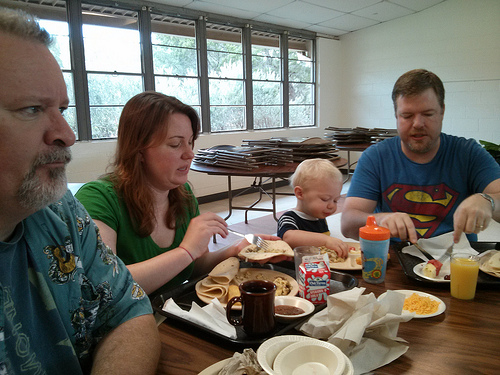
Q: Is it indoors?
A: Yes, it is indoors.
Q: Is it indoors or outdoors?
A: It is indoors.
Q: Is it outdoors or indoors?
A: It is indoors.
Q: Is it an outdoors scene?
A: No, it is indoors.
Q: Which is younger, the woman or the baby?
A: The baby is younger than the woman.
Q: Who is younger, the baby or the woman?
A: The baby is younger than the woman.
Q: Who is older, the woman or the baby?
A: The woman is older than the baby.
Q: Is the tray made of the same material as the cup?
A: Yes, both the tray and the cup are made of plastic.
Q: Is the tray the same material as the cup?
A: Yes, both the tray and the cup are made of plastic.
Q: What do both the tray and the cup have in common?
A: The material, both the tray and the cup are plastic.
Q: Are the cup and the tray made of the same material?
A: Yes, both the cup and the tray are made of plastic.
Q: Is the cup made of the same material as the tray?
A: Yes, both the cup and the tray are made of plastic.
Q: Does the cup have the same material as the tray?
A: Yes, both the cup and the tray are made of plastic.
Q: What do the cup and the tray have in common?
A: The material, both the cup and the tray are plastic.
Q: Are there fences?
A: No, there are no fences.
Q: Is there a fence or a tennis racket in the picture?
A: No, there are no fences or rackets.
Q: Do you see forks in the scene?
A: Yes, there is a fork.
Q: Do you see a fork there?
A: Yes, there is a fork.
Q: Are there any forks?
A: Yes, there is a fork.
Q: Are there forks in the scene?
A: Yes, there is a fork.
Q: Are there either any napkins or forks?
A: Yes, there is a fork.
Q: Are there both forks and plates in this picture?
A: Yes, there are both a fork and plates.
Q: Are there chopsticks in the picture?
A: No, there are no chopsticks.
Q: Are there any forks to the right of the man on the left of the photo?
A: Yes, there is a fork to the right of the man.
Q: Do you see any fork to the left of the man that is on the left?
A: No, the fork is to the right of the man.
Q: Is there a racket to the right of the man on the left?
A: No, there is a fork to the right of the man.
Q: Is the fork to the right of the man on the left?
A: Yes, the fork is to the right of the man.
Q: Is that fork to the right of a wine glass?
A: No, the fork is to the right of the man.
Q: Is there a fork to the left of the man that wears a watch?
A: Yes, there is a fork to the left of the man.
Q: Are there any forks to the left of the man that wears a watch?
A: Yes, there is a fork to the left of the man.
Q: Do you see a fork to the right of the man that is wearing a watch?
A: No, the fork is to the left of the man.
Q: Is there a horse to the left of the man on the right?
A: No, there is a fork to the left of the man.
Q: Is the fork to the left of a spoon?
A: No, the fork is to the left of the man.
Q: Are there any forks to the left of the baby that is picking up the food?
A: Yes, there is a fork to the left of the baby.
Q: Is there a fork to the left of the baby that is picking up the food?
A: Yes, there is a fork to the left of the baby.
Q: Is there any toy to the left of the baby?
A: No, there is a fork to the left of the baby.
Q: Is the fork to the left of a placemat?
A: No, the fork is to the left of the baby.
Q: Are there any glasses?
A: No, there are no glasses.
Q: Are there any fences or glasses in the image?
A: No, there are no glasses or fences.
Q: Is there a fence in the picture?
A: No, there are no fences.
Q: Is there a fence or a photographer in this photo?
A: No, there are no fences or photographers.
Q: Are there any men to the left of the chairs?
A: Yes, there is a man to the left of the chairs.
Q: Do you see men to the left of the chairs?
A: Yes, there is a man to the left of the chairs.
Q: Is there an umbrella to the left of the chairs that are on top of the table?
A: No, there is a man to the left of the chairs.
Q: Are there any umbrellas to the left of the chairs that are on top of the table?
A: No, there is a man to the left of the chairs.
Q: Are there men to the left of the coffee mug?
A: Yes, there is a man to the left of the coffee mug.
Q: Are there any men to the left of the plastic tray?
A: Yes, there is a man to the left of the tray.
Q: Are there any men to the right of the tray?
A: No, the man is to the left of the tray.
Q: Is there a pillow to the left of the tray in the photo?
A: No, there is a man to the left of the tray.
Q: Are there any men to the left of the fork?
A: Yes, there is a man to the left of the fork.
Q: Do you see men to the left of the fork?
A: Yes, there is a man to the left of the fork.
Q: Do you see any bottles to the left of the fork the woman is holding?
A: No, there is a man to the left of the fork.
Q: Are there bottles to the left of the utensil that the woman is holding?
A: No, there is a man to the left of the fork.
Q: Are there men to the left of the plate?
A: Yes, there is a man to the left of the plate.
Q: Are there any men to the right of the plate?
A: No, the man is to the left of the plate.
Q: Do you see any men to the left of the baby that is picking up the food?
A: Yes, there is a man to the left of the baby.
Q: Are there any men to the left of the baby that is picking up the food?
A: Yes, there is a man to the left of the baby.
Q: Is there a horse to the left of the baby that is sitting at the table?
A: No, there is a man to the left of the baby.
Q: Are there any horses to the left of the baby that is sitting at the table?
A: No, there is a man to the left of the baby.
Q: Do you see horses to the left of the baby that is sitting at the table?
A: No, there is a man to the left of the baby.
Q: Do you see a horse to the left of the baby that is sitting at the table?
A: No, there is a man to the left of the baby.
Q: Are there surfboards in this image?
A: No, there are no surfboards.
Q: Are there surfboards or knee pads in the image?
A: No, there are no surfboards or knee pads.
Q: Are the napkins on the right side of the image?
A: Yes, the napkins are on the right of the image.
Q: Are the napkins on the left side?
A: No, the napkins are on the right of the image.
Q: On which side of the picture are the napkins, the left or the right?
A: The napkins are on the right of the image.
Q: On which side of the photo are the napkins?
A: The napkins are on the right of the image.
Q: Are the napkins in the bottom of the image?
A: Yes, the napkins are in the bottom of the image.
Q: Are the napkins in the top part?
A: No, the napkins are in the bottom of the image.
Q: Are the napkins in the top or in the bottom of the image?
A: The napkins are in the bottom of the image.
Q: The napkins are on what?
A: The napkins are on the table.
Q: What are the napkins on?
A: The napkins are on the table.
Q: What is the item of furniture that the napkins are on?
A: The piece of furniture is a table.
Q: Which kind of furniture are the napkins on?
A: The napkins are on the table.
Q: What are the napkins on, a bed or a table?
A: The napkins are on a table.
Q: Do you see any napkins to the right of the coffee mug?
A: Yes, there are napkins to the right of the coffee mug.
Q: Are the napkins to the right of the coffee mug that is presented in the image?
A: Yes, the napkins are to the right of the coffee mug.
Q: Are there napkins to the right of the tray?
A: Yes, there are napkins to the right of the tray.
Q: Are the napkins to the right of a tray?
A: Yes, the napkins are to the right of a tray.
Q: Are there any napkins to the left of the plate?
A: No, the napkins are to the right of the plate.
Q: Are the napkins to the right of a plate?
A: Yes, the napkins are to the right of a plate.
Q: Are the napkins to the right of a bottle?
A: No, the napkins are to the right of a plate.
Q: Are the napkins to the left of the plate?
A: No, the napkins are to the right of the plate.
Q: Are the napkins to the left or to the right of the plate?
A: The napkins are to the right of the plate.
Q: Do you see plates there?
A: Yes, there is a plate.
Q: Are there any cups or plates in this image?
A: Yes, there is a plate.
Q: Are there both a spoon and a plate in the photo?
A: No, there is a plate but no spoons.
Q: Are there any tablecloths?
A: No, there are no tablecloths.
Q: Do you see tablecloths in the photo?
A: No, there are no tablecloths.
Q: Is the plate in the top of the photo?
A: No, the plate is in the bottom of the image.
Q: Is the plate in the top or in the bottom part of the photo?
A: The plate is in the bottom of the image.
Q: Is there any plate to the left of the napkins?
A: Yes, there is a plate to the left of the napkins.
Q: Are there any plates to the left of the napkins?
A: Yes, there is a plate to the left of the napkins.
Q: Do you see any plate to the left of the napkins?
A: Yes, there is a plate to the left of the napkins.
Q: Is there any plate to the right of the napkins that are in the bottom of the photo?
A: No, the plate is to the left of the napkins.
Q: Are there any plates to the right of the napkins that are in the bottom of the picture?
A: No, the plate is to the left of the napkins.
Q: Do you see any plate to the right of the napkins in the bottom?
A: No, the plate is to the left of the napkins.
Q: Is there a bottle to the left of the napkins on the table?
A: No, there is a plate to the left of the napkins.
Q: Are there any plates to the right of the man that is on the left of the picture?
A: Yes, there is a plate to the right of the man.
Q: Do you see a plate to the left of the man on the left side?
A: No, the plate is to the right of the man.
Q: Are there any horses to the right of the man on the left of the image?
A: No, there is a plate to the right of the man.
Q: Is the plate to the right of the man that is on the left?
A: Yes, the plate is to the right of the man.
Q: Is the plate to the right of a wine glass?
A: No, the plate is to the right of the man.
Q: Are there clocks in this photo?
A: No, there are no clocks.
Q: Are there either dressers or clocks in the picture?
A: No, there are no clocks or dressers.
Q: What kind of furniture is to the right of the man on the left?
A: The pieces of furniture are chairs.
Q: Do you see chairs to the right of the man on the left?
A: Yes, there are chairs to the right of the man.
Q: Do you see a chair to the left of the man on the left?
A: No, the chairs are to the right of the man.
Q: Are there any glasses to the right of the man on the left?
A: No, there are chairs to the right of the man.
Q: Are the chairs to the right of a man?
A: Yes, the chairs are to the right of a man.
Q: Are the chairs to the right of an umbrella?
A: No, the chairs are to the right of a man.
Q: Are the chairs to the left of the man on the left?
A: No, the chairs are to the right of the man.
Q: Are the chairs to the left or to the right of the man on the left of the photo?
A: The chairs are to the right of the man.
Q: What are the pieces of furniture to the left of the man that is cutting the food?
A: The pieces of furniture are chairs.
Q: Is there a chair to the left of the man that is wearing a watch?
A: Yes, there are chairs to the left of the man.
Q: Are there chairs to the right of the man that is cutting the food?
A: No, the chairs are to the left of the man.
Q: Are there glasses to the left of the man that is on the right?
A: No, there are chairs to the left of the man.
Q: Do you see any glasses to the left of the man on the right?
A: No, there are chairs to the left of the man.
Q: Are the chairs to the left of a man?
A: Yes, the chairs are to the left of a man.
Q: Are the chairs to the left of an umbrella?
A: No, the chairs are to the left of a man.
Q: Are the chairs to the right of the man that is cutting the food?
A: No, the chairs are to the left of the man.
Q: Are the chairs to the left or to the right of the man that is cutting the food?
A: The chairs are to the left of the man.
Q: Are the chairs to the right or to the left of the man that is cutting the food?
A: The chairs are to the left of the man.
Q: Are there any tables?
A: Yes, there is a table.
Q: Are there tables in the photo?
A: Yes, there is a table.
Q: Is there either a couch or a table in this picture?
A: Yes, there is a table.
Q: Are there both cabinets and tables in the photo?
A: No, there is a table but no cabinets.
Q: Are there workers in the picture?
A: No, there are no workers.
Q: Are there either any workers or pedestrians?
A: No, there are no workers or pedestrians.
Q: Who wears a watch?
A: The man wears a watch.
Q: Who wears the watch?
A: The man wears a watch.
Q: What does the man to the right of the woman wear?
A: The man wears a watch.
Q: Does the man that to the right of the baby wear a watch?
A: Yes, the man wears a watch.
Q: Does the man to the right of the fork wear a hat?
A: No, the man wears a watch.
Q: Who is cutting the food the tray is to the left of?
A: The man is cutting the food.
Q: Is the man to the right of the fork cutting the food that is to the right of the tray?
A: Yes, the man is cutting the food.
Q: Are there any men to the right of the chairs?
A: Yes, there is a man to the right of the chairs.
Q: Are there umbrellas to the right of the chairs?
A: No, there is a man to the right of the chairs.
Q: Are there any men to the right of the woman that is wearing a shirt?
A: Yes, there is a man to the right of the woman.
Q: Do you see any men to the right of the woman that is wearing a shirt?
A: Yes, there is a man to the right of the woman.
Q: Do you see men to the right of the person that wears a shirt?
A: Yes, there is a man to the right of the woman.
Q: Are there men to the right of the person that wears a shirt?
A: Yes, there is a man to the right of the woman.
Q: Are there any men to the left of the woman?
A: No, the man is to the right of the woman.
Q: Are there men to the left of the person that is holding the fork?
A: No, the man is to the right of the woman.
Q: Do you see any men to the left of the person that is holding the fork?
A: No, the man is to the right of the woman.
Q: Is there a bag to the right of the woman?
A: No, there is a man to the right of the woman.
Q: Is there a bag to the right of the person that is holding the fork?
A: No, there is a man to the right of the woman.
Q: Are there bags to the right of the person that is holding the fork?
A: No, there is a man to the right of the woman.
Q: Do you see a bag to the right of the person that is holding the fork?
A: No, there is a man to the right of the woman.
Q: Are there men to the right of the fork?
A: Yes, there is a man to the right of the fork.